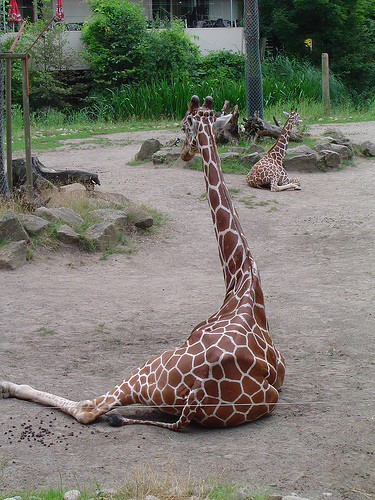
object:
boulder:
[286, 142, 341, 173]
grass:
[32, 120, 132, 151]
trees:
[257, 0, 374, 95]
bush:
[79, 0, 206, 94]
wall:
[169, 25, 246, 74]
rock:
[317, 147, 340, 168]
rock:
[134, 138, 160, 163]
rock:
[151, 143, 184, 166]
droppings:
[0, 411, 75, 451]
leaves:
[109, 11, 153, 47]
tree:
[80, 0, 149, 87]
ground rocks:
[78, 204, 126, 254]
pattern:
[191, 320, 264, 376]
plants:
[152, 53, 267, 122]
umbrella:
[5, 0, 23, 33]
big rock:
[0, 211, 48, 269]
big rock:
[54, 223, 77, 245]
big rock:
[81, 221, 119, 250]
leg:
[14, 347, 196, 427]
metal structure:
[0, 51, 37, 205]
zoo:
[0, 0, 374, 497]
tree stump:
[238, 107, 305, 144]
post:
[321, 51, 330, 121]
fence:
[241, 0, 262, 124]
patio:
[0, 0, 244, 29]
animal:
[0, 95, 286, 431]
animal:
[245, 106, 302, 192]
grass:
[44, 194, 162, 263]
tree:
[240, 0, 264, 116]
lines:
[143, 332, 234, 399]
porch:
[0, 20, 248, 84]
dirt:
[1, 120, 373, 499]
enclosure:
[0, 55, 368, 144]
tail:
[123, 386, 200, 432]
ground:
[0, 121, 375, 490]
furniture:
[195, 18, 225, 26]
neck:
[197, 139, 252, 261]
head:
[178, 94, 216, 162]